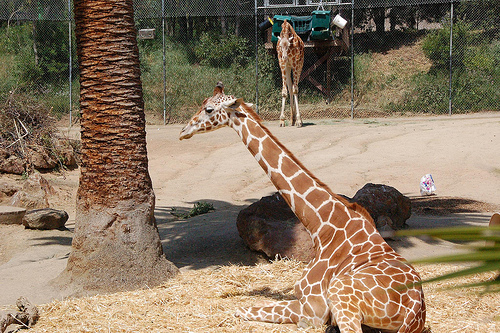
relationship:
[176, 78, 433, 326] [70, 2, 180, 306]
giraffe next to tree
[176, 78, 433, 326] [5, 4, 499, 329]
giraffe in zoo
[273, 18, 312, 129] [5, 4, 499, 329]
giraffe in zoo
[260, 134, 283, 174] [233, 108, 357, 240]
spot on neck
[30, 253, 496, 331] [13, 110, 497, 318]
hay on ground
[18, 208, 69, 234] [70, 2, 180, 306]
rock behind tree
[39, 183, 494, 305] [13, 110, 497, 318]
shadow on ground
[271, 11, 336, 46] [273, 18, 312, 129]
feeder behind giraffe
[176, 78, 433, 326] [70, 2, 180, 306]
giraffe sitting under tree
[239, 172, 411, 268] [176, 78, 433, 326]
rocks behind giraffe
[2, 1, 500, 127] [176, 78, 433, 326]
fence contains giraffe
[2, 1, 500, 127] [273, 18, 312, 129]
fence contains giraffe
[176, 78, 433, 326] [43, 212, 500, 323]
giraffe on grass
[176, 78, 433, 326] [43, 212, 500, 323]
giraffe laying on grass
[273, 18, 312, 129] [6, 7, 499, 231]
giraffe in background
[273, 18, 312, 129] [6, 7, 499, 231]
giraffe standing in background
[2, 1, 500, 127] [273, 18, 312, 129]
fence behind giraffe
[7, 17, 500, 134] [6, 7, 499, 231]
trees in background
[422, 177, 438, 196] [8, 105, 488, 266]
bag on dirt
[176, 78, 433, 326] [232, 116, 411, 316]
giraffe has spots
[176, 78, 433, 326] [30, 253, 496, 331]
giraffe laying on hay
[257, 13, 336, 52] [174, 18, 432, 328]
feeder for animals